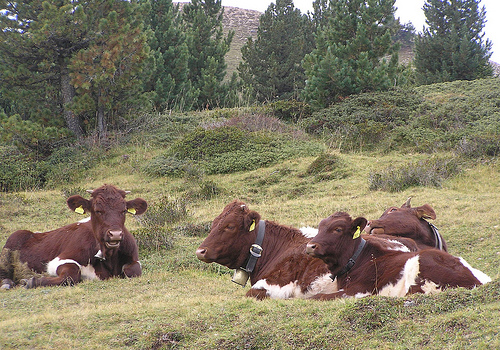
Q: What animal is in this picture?
A: Cows.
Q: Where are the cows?
A: In a pasture.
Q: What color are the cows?
A: Brown and white.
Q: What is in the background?
A: Trees and foliage.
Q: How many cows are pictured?
A: Four.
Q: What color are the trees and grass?
A: Green.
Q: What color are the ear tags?
A: Yellow.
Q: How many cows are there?
A: Four.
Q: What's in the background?
A: Trees.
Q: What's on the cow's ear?
A: Yellow tags.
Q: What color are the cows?
A: Brown and white.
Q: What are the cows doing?
A: Lying in the grass.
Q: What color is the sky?
A: White.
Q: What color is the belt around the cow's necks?
A: Black.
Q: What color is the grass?
A: Green and yellow.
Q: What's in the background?
A: A mountain.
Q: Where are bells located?
A: On the cow's necks.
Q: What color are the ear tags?
A: Yellow.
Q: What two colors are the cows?
A: Brown and white.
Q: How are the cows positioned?
A: Laying down.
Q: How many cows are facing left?
A: 2.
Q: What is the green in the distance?
A: Trees.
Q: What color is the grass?
A: Green.